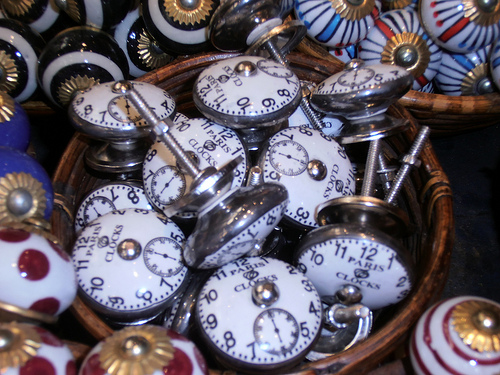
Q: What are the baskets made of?
A: Wicker.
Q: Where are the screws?
A: In the baskets.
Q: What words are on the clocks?
A: Paris clocks.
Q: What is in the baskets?
A: Knobs for furniture.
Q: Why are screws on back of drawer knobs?
A: To attach to drawers.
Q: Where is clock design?
A: On knobs in front basket.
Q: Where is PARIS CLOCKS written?
A: On knobs in front basket.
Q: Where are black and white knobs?
A: Basket in upper left corner.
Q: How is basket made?
A: Made of wicker.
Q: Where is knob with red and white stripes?
A: Lower right hand corner.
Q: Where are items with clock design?
A: In brown wicker basket.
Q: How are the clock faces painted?
A: White.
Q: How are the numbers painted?
A: Black.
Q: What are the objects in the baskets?
A: Knobs.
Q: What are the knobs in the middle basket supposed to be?
A: Clocks.